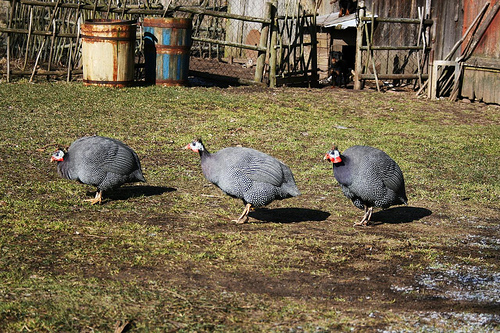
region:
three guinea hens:
[46, 137, 407, 229]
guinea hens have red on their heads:
[319, 142, 354, 174]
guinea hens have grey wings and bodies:
[224, 139, 309, 207]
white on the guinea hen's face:
[185, 138, 209, 155]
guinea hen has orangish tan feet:
[78, 189, 123, 204]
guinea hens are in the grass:
[70, 178, 115, 207]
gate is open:
[245, 23, 388, 93]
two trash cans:
[66, 15, 222, 100]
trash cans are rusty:
[73, 9, 207, 86]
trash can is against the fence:
[158, 23, 257, 83]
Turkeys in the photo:
[42, 132, 409, 239]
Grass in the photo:
[252, 103, 349, 143]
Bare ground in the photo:
[270, 262, 371, 292]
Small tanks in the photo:
[79, 20, 132, 90]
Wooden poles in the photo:
[254, 31, 276, 87]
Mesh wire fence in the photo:
[190, 44, 254, 81]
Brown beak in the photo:
[180, 144, 189, 156]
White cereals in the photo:
[404, 267, 498, 307]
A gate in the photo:
[280, 12, 319, 80]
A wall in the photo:
[454, 14, 497, 101]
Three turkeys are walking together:
[41, 77, 449, 263]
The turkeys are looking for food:
[30, 77, 415, 253]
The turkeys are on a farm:
[32, 108, 487, 298]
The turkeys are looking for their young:
[31, 87, 477, 305]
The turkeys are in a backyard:
[8, 85, 474, 281]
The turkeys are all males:
[38, 78, 463, 273]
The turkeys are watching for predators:
[15, 77, 451, 259]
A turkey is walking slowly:
[35, 113, 165, 221]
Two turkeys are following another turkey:
[27, 93, 437, 248]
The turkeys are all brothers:
[30, 84, 435, 270]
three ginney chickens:
[36, 129, 444, 209]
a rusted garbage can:
[71, 14, 135, 91]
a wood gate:
[268, 7, 323, 91]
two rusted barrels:
[68, 12, 196, 82]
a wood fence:
[347, 13, 434, 90]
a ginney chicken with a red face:
[323, 135, 420, 240]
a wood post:
[248, 3, 276, 88]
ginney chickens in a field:
[26, 137, 434, 234]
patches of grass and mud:
[206, 249, 397, 311]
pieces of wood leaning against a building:
[426, 8, 493, 103]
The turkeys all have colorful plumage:
[40, 85, 455, 260]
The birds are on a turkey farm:
[23, 77, 449, 265]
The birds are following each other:
[35, 82, 451, 312]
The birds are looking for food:
[15, 57, 440, 287]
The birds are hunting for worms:
[35, 80, 435, 266]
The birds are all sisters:
[31, 103, 456, 269]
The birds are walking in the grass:
[30, 70, 465, 287]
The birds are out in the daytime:
[35, 100, 435, 271]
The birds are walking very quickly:
[31, 97, 441, 278]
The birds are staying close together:
[26, 83, 455, 270]